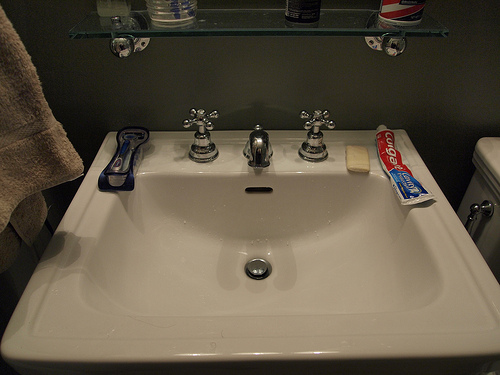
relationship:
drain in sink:
[243, 257, 273, 281] [2, 102, 497, 373]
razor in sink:
[99, 126, 149, 189] [2, 102, 497, 373]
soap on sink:
[345, 143, 368, 174] [59, 91, 474, 367]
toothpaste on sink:
[374, 121, 435, 207] [9, 127, 485, 356]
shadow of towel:
[40, 229, 110, 285] [2, 5, 84, 271]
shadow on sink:
[40, 229, 110, 285] [9, 127, 485, 356]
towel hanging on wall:
[9, 23, 97, 235] [5, 12, 50, 306]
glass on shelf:
[140, 1, 196, 26] [67, 8, 462, 59]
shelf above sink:
[67, 8, 462, 59] [108, 132, 380, 302]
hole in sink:
[244, 186, 273, 194] [2, 129, 498, 373]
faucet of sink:
[173, 107, 344, 176] [2, 102, 497, 373]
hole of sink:
[242, 182, 277, 197] [2, 102, 497, 373]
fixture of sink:
[237, 120, 277, 170] [2, 102, 497, 373]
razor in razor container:
[114, 124, 140, 179] [98, 127, 150, 191]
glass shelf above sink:
[75, 15, 450, 52] [18, 170, 496, 352]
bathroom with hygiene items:
[17, 15, 496, 358] [364, 110, 436, 226]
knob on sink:
[295, 105, 339, 138] [2, 102, 497, 373]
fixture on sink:
[241, 122, 275, 168] [2, 102, 497, 373]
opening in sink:
[242, 183, 286, 199] [18, 111, 496, 352]